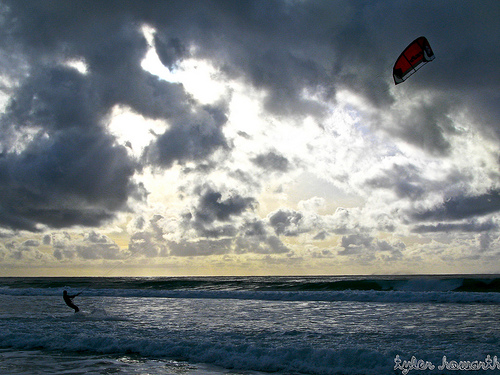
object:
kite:
[390, 35, 439, 86]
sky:
[0, 0, 499, 275]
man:
[63, 289, 84, 314]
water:
[0, 291, 499, 374]